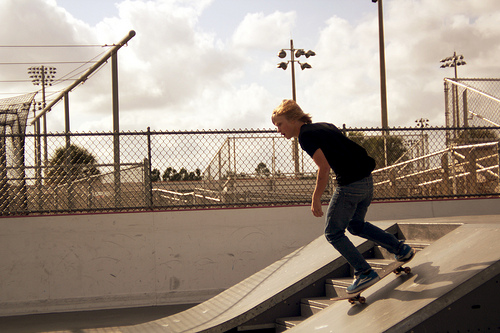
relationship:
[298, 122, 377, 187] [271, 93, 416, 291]
shirt on skater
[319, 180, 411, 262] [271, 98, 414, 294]
jeans on boy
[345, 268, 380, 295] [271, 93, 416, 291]
shoe on skater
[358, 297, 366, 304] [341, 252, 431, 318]
wheel on skateboard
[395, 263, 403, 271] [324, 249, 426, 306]
wheel of skateboard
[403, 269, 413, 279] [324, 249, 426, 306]
wheel of skateboard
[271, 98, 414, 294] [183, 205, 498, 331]
boy skating on ramp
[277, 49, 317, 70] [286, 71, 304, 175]
light on pole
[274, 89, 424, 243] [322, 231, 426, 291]
boy on skateboard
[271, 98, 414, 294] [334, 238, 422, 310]
boy on skateboard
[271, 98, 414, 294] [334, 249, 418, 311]
boy on skateboard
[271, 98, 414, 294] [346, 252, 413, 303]
boy riding skateboard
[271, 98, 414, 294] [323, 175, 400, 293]
boy wearing jeans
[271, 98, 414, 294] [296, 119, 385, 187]
boy wearing shirt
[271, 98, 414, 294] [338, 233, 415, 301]
boy wearing shoes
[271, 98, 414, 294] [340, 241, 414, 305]
boy wearing shoes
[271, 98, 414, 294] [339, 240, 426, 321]
boy wearing shoes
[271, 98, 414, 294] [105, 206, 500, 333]
boy skateboarding down cement ramp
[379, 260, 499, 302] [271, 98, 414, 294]
shadow of boy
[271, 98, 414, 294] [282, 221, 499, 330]
boy on ramp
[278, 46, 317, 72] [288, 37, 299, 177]
light on pole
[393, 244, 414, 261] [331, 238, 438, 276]
shoe on skateboard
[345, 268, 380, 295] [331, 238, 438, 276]
shoe on skateboard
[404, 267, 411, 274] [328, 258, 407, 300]
wheel on skateboard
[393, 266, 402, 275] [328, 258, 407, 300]
wheel on skateboard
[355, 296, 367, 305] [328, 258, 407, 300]
wheel on skateboard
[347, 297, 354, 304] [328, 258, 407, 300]
wheel on skateboard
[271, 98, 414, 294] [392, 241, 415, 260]
boy wearing shoe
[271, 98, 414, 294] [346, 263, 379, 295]
boy wearing shoe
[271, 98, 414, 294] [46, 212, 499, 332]
boy going down cement ramp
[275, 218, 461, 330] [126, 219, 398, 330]
stairs next to ramp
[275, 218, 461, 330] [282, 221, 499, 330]
stairs next to ramp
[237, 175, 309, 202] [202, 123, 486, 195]
area separated by fence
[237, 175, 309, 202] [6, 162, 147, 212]
area separated by fence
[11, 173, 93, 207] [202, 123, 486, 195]
area separated by fence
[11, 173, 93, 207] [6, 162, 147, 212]
area separated by fence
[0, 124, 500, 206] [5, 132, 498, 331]
railings throughout park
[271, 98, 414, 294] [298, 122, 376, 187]
boy wearing shirt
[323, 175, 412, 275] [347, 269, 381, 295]
jeans worn with shoe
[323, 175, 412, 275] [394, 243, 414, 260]
jeans worn with shoe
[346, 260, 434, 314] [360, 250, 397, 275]
shadow from skateboard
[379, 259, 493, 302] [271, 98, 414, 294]
shadow from boy